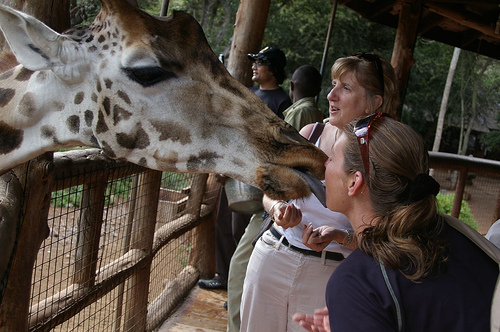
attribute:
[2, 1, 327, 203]
giraffe — friendly, brown, white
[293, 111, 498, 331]
lady — brunette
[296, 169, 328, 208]
tongue — grey, long, blue, black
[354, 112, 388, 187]
sunglasses — red, brown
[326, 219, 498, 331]
shirt — blue, dark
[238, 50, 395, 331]
lady — white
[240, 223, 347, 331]
pants — white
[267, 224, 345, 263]
belt — black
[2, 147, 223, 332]
fence — wood, wire mesh, meshed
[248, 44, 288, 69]
cap — black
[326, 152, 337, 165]
eyes — closed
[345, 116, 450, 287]
hair — blonde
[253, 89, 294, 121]
shirt — gray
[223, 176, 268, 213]
bucket — grey, tin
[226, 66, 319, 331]
male — african-american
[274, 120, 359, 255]
tank top — white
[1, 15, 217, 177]
spots — brown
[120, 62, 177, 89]
eye — black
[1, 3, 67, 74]
ear — pointy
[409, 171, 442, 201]
scrunchie — black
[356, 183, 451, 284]
ponytail — long, brown